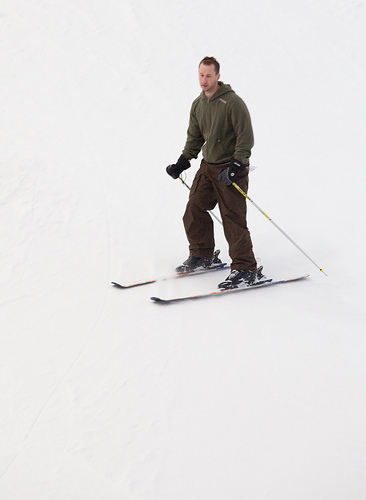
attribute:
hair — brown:
[195, 55, 219, 71]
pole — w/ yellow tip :
[222, 178, 325, 272]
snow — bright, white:
[0, 7, 363, 498]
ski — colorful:
[109, 254, 261, 287]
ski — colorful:
[149, 270, 310, 304]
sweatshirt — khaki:
[181, 80, 254, 163]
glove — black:
[165, 154, 191, 179]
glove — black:
[214, 157, 245, 186]